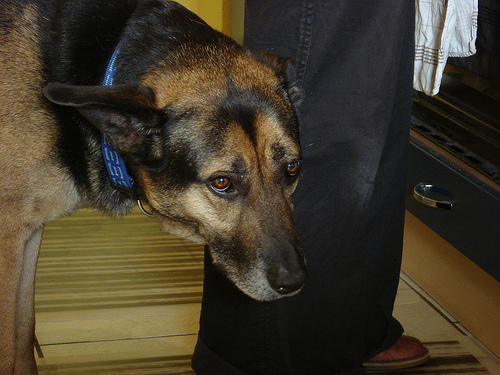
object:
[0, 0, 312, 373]
dog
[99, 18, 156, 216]
collar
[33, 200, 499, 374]
carpet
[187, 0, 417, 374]
jeans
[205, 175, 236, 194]
eyes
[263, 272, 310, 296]
nose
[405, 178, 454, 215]
handle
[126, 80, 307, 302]
face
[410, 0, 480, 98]
hand towel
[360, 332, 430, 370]
shoe